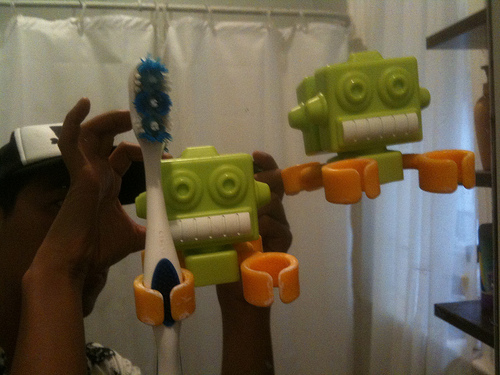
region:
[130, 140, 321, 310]
A green smiling toy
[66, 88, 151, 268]
A person's hand holding a toy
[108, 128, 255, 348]
Part of a toothbrush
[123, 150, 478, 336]
A toothbrush and a green toy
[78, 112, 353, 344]
A green toy with a holder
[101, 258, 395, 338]
Two orange holders together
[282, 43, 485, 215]
Green toy with white teeth and orange hands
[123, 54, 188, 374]
toothbrush held by one of the toys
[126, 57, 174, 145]
blue and white bristles of toothbrush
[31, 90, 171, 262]
boy's hand holding one of toys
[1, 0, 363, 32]
Rail bar of shower curtain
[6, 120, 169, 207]
Hat of boy holding toys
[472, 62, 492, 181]
Lotion bottle on bathroom stand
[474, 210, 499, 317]
Can of something on stand in bathroom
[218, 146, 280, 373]
Left arm of boy holding toys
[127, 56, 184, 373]
A white toothbrush with blue on it.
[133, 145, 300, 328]
A green robot head with orange hands holding a toothbrush.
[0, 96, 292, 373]
A person with their hands up.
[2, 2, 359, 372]
A white shower curtain.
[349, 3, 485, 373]
A long white curtain over the window.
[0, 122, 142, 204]
Black and white hat.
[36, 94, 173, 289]
A man's right hand.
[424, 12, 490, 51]
A top wooden shelf.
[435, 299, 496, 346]
A bottom dark wooden shelf.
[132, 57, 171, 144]
Blue bristles on a toothbrush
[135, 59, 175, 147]
The bristles of the toothbrush.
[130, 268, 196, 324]
The orange clip grasping the toothbrush.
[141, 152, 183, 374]
The handle of the toothbrush.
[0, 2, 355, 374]
The shower curtain behind the guy.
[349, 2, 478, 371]
The white curtain on the window.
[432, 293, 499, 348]
The black shelf on the right.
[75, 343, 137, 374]
The black and white shirt sleeve of the guy.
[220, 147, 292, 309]
The right hand of the guy.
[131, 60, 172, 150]
The bristles of the toothbrush.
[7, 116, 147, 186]
The black and white hat the guy is wearing.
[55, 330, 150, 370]
The white and black shirt the guy is wearing.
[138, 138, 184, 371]
The handle of the toothbrush.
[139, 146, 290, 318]
The robot toothbrush holder on the left.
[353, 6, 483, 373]
The curtain on the window.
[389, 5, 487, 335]
The window in the room.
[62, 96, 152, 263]
The left hand of the guy.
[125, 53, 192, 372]
a blue toothbrush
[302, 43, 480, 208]
a robot toothbrush holder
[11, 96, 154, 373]
a hand holding something